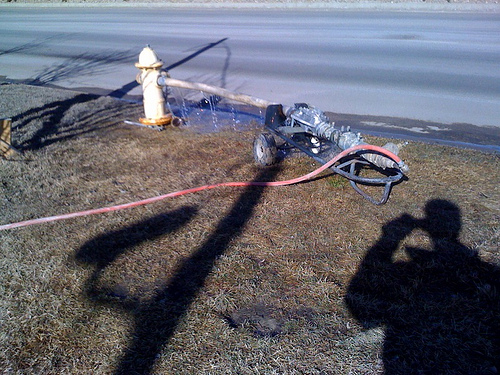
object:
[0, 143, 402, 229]
hose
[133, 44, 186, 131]
fire hyrdrant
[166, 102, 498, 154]
water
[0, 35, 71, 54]
shadow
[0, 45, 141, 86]
shadow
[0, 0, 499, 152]
pavement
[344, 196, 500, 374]
shadow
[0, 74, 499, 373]
brown grass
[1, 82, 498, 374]
dried out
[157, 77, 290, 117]
hose